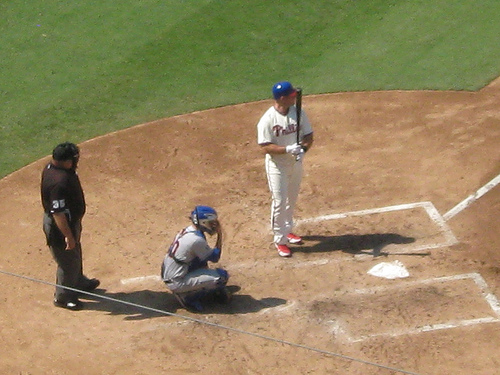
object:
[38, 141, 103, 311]
umpire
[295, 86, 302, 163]
bat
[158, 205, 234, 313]
player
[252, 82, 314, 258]
player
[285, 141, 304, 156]
hands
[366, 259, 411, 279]
plate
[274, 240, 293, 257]
shoes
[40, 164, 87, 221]
shirt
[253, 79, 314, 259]
man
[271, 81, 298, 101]
hat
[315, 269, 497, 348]
box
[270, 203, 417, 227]
lines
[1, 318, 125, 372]
ground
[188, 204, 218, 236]
helmet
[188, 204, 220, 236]
catcher's helmet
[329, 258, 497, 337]
batters box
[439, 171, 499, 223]
line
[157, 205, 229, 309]
baseball uniform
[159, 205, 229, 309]
uniform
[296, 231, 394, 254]
shadow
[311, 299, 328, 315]
dirt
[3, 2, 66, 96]
grass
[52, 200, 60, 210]
number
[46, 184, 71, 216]
sleeve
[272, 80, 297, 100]
helmet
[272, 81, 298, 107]
head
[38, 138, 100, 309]
man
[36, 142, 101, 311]
baseball umpire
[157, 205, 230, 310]
catcher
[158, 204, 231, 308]
man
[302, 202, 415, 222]
chalk